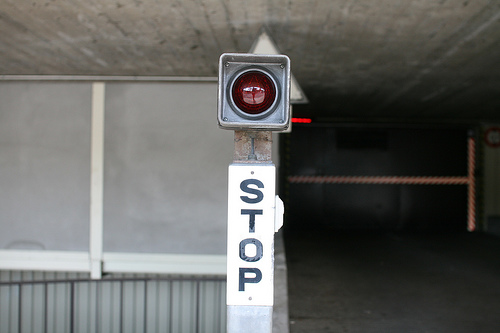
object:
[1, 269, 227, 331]
railing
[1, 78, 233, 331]
wall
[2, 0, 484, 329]
building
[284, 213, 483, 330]
flooring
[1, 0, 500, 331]
area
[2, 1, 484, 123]
ceiling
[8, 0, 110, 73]
groove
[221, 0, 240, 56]
groove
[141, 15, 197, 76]
groove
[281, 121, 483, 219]
wall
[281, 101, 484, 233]
background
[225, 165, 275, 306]
sign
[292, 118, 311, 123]
illumination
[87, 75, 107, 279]
line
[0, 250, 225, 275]
frame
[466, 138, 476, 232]
pole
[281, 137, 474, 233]
pole barrier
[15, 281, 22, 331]
fence post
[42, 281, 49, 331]
fence post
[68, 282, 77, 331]
fence post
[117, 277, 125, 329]
fence post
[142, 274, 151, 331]
fence post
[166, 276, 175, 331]
fence post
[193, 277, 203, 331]
fence post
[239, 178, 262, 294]
letter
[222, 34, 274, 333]
post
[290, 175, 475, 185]
bar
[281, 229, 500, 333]
road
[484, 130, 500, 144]
sign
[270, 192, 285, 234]
paint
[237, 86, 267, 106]
reflection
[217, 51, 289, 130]
light